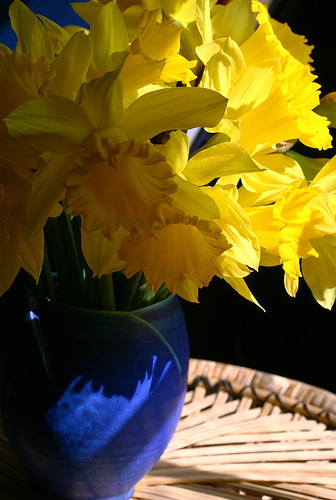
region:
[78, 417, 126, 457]
the vase is blue in color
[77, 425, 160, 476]
the vase is made of glass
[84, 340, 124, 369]
this is a shadow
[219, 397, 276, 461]
this is a basket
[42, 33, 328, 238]
these are some flowers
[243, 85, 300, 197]
the flowers are yellow in color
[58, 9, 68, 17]
the area is blue in color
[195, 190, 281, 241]
the flowers are big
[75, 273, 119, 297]
the stalks are green in color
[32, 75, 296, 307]
the flowers are yellow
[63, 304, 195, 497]
the vase is blue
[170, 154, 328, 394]
the sun is shining here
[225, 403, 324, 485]
this is a wicker table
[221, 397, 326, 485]
the table is brown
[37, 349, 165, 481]
this is a vase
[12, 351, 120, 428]
the vase is made of glass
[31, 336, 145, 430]
the vase is blue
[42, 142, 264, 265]
the flowers are yellow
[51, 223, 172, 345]
the flower stems are green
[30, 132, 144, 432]
this area is shaded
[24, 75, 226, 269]
a bright yellow daffodil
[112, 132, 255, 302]
a bright yellow daffodil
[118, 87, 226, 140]
a leaf on a stem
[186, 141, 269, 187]
a leaf on a stem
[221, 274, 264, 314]
a leaf on a stem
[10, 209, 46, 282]
a leaf on a stem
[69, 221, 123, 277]
a leaf on a stem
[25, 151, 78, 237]
a leaf on a stem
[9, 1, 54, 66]
a leaf on a stem